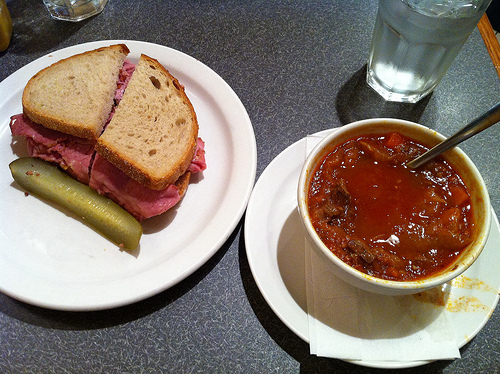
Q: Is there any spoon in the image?
A: Yes, there is a spoon.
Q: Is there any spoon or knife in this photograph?
A: Yes, there is a spoon.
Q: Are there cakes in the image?
A: No, there are no cakes.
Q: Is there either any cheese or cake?
A: No, there are no cakes or cheese.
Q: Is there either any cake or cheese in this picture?
A: No, there are no cakes or cheese.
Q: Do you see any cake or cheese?
A: No, there are no cakes or cheese.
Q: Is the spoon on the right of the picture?
A: Yes, the spoon is on the right of the image.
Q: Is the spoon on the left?
A: No, the spoon is on the right of the image.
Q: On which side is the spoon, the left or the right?
A: The spoon is on the right of the image.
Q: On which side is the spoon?
A: The spoon is on the right of the image.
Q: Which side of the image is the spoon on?
A: The spoon is on the right of the image.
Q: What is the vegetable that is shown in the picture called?
A: The vegetable is chili.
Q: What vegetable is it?
A: The vegetable is chili.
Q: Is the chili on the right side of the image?
A: Yes, the chili is on the right of the image.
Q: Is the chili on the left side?
A: No, the chili is on the right of the image.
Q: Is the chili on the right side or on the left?
A: The chili is on the right of the image.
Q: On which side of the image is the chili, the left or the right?
A: The chili is on the right of the image.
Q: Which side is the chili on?
A: The chili is on the right of the image.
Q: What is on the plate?
A: The chili is on the plate.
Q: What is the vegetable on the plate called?
A: The vegetable is chili.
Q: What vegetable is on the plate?
A: The vegetable is chili.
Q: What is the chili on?
A: The chili is on the plate.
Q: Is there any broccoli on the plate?
A: No, there is chili on the plate.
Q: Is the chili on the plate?
A: Yes, the chili is on the plate.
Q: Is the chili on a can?
A: No, the chili is on the plate.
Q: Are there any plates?
A: Yes, there is a plate.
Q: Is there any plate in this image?
A: Yes, there is a plate.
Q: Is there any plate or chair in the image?
A: Yes, there is a plate.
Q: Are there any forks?
A: No, there are no forks.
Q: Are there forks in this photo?
A: No, there are no forks.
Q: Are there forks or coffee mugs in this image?
A: No, there are no forks or coffee mugs.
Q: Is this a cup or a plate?
A: This is a plate.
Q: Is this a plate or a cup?
A: This is a plate.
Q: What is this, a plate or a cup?
A: This is a plate.